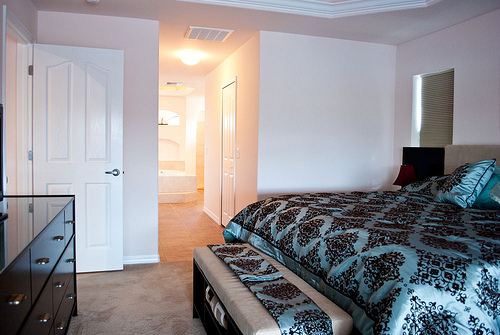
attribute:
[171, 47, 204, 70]
light — on, bright, blue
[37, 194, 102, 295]
dresser — brown, black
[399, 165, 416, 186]
lamp — red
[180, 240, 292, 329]
bench — blue, tan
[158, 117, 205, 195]
bathroom — doorless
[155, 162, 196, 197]
bathtub — big, white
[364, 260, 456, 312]
bedspread — black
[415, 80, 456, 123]
window — white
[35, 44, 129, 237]
door — white, open, closed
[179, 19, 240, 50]
vent — white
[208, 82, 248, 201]
door — tall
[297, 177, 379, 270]
blanket — blue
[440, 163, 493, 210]
pillow — shiny, blue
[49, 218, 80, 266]
drawer — wooden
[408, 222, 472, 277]
comforter — blue